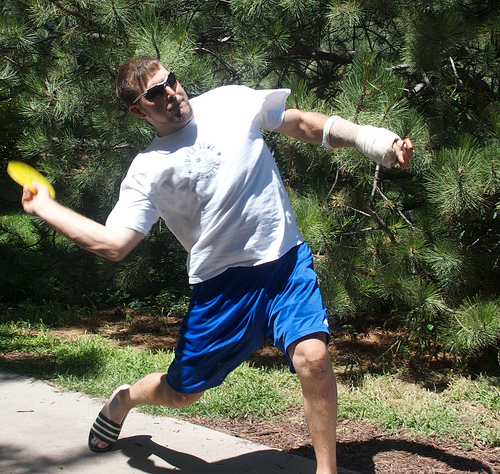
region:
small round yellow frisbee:
[1, 152, 114, 239]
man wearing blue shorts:
[151, 242, 336, 398]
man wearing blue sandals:
[74, 385, 140, 455]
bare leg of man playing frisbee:
[274, 327, 353, 467]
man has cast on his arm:
[322, 86, 428, 183]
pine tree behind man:
[25, 15, 491, 360]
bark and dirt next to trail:
[283, 400, 493, 470]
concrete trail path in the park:
[9, 359, 349, 471]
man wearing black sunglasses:
[121, 57, 187, 104]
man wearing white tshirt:
[98, 71, 337, 283]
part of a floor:
[205, 439, 224, 451]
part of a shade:
[401, 434, 423, 458]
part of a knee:
[307, 354, 328, 378]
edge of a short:
[182, 369, 232, 399]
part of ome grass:
[218, 388, 243, 410]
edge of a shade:
[219, 443, 251, 465]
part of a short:
[215, 307, 260, 368]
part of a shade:
[221, 425, 272, 466]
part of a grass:
[92, 342, 120, 379]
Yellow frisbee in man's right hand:
[3, 153, 59, 203]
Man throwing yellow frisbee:
[10, 55, 416, 470]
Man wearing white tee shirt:
[83, 80, 308, 285]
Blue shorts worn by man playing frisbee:
[162, 242, 332, 393]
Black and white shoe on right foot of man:
[85, 410, 121, 452]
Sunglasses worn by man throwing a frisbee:
[115, 67, 185, 105]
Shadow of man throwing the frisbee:
[116, 430, 491, 470]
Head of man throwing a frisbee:
[110, 53, 191, 128]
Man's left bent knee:
[270, 305, 357, 466]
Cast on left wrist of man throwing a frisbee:
[317, 116, 401, 166]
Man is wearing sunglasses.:
[107, 47, 211, 147]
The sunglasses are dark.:
[113, 44, 212, 134]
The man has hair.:
[111, 46, 196, 137]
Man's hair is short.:
[115, 55, 195, 140]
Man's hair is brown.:
[110, 40, 203, 138]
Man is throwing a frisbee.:
[4, 50, 430, 255]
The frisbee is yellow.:
[8, 150, 56, 209]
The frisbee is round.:
[6, 155, 64, 227]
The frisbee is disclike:
[4, 153, 66, 218]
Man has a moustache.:
[109, 48, 209, 140]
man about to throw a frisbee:
[5, 154, 61, 220]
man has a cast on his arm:
[293, 107, 418, 171]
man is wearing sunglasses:
[108, 51, 202, 143]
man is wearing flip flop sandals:
[79, 375, 144, 457]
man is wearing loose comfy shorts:
[160, 243, 342, 409]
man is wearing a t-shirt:
[108, 76, 305, 297]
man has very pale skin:
[277, 320, 355, 472]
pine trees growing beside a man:
[319, 3, 497, 468]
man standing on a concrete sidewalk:
[1, 343, 431, 472]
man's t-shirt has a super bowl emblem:
[166, 129, 237, 201]